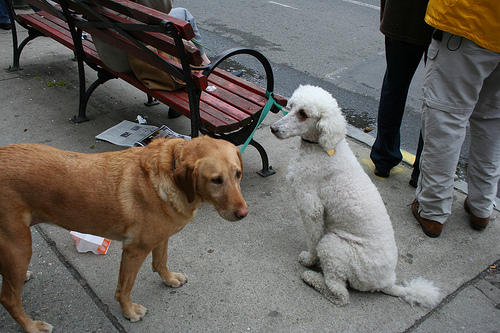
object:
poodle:
[269, 84, 439, 310]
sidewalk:
[0, 0, 499, 333]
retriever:
[0, 135, 249, 333]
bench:
[7, 0, 288, 177]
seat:
[18, 9, 287, 127]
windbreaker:
[424, 0, 498, 54]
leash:
[240, 89, 288, 153]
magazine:
[95, 120, 191, 148]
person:
[370, 0, 443, 189]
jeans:
[370, 34, 432, 180]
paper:
[70, 230, 111, 255]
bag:
[128, 39, 202, 91]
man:
[406, 0, 498, 237]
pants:
[415, 27, 500, 224]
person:
[87, 0, 242, 78]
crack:
[34, 224, 125, 332]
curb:
[343, 123, 499, 210]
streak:
[362, 149, 416, 180]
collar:
[301, 137, 336, 156]